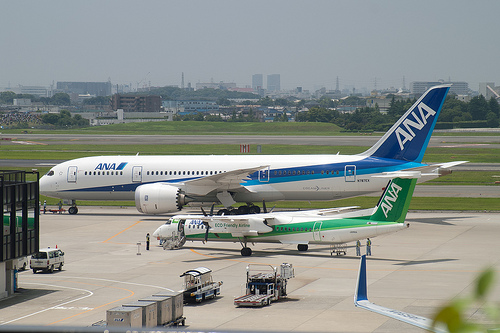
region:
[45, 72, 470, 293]
An airport tarmac.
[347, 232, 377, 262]
Two people are standing next to the plane.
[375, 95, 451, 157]
The name of the airline.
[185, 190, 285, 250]
The plain has propellers.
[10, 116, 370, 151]
The runway.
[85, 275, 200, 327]
Cargo.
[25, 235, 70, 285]
A white van.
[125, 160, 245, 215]
The plane's engine.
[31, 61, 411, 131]
A city in the background.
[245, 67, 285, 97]
Two high-rise buildings in the distance.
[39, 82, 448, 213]
a blue and white airplane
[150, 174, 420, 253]
a green and white airplane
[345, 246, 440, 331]
a blue and white airplane wing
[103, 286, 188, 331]
a silver luggage cart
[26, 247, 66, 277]
a parked white van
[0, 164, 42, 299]
an airport buliding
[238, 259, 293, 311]
an airport luggage vehicle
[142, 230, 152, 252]
a person standing on tarmac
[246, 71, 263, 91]
tall skyscraper in distance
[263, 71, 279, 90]
tall skyscraper in distance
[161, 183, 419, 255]
Airplane with a green strip and rudder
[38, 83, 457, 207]
Airplane with a blue strip and rudder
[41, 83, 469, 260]
Large airplne next to an airplane a third of its size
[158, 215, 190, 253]
Open airplane door with stairs lowered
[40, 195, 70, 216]
Two people standing under the plane's nose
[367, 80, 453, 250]
Two airplane rudders steciled with ANA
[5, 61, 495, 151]
City skyline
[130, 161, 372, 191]
Three emergency exits on an airplane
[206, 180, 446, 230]
Wording on a plane declaring ANA an ECO friendly airline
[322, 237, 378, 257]
Two people with a luggage cart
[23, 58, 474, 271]
Two airplanes are parked next to each other.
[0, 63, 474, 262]
Two airplanes are facing the same direction.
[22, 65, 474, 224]
One airplane's colors are white and blue.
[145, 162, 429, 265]
An airplane's colors are white and green.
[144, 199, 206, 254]
An airplane's door is open.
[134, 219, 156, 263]
a person is standing next to an airplane.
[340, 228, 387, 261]
Two people are next to an aircraft.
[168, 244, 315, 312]
Two service vehicles are near an airplane.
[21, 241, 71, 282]
A van is parked at an airport terminal.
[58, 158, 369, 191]
Doors are visible on an aircraft.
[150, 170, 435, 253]
smaller green and white plane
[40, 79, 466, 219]
larger blue and white plane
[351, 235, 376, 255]
2 guys behind green plane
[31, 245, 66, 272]
white van parked to the left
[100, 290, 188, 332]
chain of luggage carts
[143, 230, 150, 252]
person in front of green plane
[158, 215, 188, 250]
open plane door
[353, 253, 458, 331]
plane wing in corner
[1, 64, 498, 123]
city behind airport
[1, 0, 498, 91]
dark gray cloudy sky